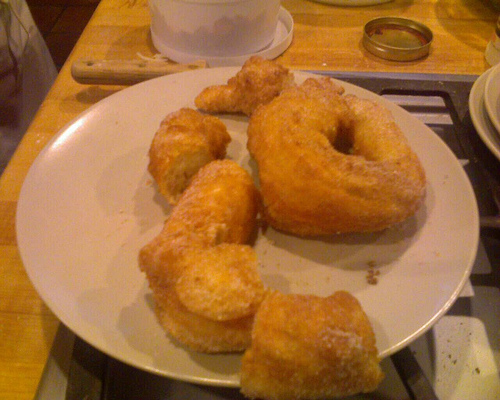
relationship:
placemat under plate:
[36, 70, 497, 396] [19, 46, 477, 386]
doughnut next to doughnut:
[124, 100, 264, 201] [235, 77, 447, 221]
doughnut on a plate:
[248, 75, 428, 231] [36, 77, 498, 359]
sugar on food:
[171, 174, 202, 215] [141, 150, 287, 320]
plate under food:
[55, 210, 172, 359] [141, 137, 360, 397]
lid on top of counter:
[351, 10, 438, 57] [80, 8, 497, 81]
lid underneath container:
[136, 6, 316, 68] [134, 3, 297, 60]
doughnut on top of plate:
[248, 75, 428, 231] [19, 46, 477, 386]